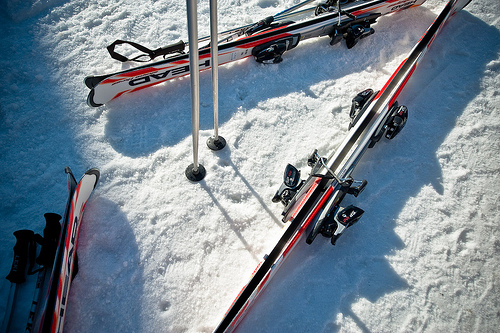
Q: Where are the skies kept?
A: In the snow.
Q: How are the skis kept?
A: In pairs.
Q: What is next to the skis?
A: Ski poles.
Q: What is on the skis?
A: Straps.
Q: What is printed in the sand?
A: Foot prints.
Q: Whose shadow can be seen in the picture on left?
A: A Person.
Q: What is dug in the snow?
A: Ski poles.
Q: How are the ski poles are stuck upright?
A: Two.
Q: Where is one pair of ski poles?
A: Planted in the snow by the skis.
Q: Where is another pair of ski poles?
A: In the bottom left of the picture.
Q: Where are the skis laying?
A: They are laying in the snow.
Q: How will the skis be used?
A: For downhill skiing.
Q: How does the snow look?
A: Looks powdery and white.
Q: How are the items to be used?
A: For downhill skiing.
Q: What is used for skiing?
A: Two skis and two poles.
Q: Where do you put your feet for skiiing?
A: The feet go inside the skis.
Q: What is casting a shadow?
A: The poles for skiing.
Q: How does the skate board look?
A: It is red in color.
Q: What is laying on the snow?
A: The skis are laying in the snow.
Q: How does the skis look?
A: They are red in color.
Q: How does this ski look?
A: The ski is red and white.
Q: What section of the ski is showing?
A: The tail of the ski.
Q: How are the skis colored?
A: Red, white, black.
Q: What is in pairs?
A: Ski poles.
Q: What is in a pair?
A: Ski poles.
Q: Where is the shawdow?
A: Beside the skis.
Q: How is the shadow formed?
A: The sun.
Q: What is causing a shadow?
A: Skis.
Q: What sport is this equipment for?
A: Skiing.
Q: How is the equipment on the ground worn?
A: Feet.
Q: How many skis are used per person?
A: 2.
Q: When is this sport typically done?
A: Winter.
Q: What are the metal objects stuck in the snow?
A: Ski poles.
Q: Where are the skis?
A: On the ground.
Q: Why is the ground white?
A: Snow.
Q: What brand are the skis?
A: Head.